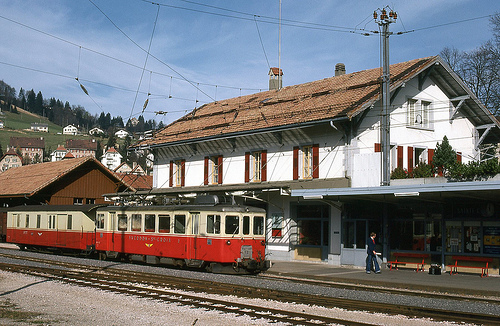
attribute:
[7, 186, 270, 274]
tram — big, orange, stopped, red, white, black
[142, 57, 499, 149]
roof — brown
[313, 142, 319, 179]
shutter — red, brown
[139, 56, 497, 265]
building — white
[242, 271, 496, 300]
track — brown, pair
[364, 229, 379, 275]
person — waiting, walking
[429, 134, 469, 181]
plant — green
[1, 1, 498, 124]
sky — clear, blue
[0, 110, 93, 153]
grass — green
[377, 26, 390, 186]
pole — wooden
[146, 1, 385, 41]
wire — electrical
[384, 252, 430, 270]
bench — red